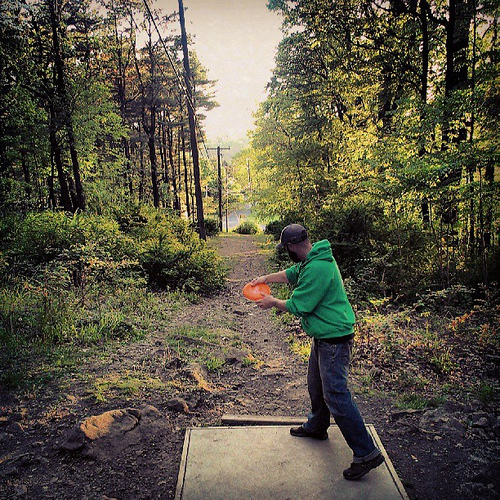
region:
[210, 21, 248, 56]
this is the sky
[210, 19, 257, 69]
the sky is bright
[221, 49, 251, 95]
the sky has clouds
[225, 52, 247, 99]
the clouds are white in color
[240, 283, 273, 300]
this is a frisbee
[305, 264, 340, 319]
the hood is green in color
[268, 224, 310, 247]
this is a cap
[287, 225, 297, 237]
the cap is black in color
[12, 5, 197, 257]
these are some trees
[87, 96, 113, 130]
the leaves are green in color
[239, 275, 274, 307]
An orange colored freesbee.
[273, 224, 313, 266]
A man wearing a black cap.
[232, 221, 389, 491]
A man in a green jacket.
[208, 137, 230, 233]
A telephone communications pole.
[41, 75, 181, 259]
Green foiliage in the woods.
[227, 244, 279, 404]
A bare dirt road.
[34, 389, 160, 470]
Footprints in the side of the road.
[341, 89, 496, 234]
The sun shining through the trees.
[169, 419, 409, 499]
A wooden platform in the woods.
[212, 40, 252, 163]
A gray colored sky with no clouds.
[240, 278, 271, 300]
an orange colored Frisbee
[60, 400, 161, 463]
brown colored rocks on the ground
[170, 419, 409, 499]
a wooden platform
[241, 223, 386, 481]
a man wearing blue jeans and a cap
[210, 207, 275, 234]
a body of water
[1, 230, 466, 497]
a dirt path in the woods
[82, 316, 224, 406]
green grass growing on the dirt path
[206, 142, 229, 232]
a utility pole beside the dirt path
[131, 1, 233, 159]
utility lines overhead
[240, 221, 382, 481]
a man wearing a green shirt and holding a Frisbee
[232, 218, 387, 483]
man is throwing a frisbee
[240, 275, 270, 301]
the frisbee is orange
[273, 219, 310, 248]
man is wearing a hat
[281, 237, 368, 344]
man's hoodie is green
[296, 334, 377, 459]
man is wearing blue jeans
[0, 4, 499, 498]
man is standing in the woods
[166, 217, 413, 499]
man is standing on concrete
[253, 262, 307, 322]
man's sleeves are pulled back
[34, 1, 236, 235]
electricity poles on side of forest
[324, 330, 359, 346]
man's undershirt is black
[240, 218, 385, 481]
this is a person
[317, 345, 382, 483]
this is a person's leg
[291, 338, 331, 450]
this is a person's leg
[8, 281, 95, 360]
this is a green vegetation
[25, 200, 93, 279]
this is a green vegetation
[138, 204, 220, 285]
this is a green vegetation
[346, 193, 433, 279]
this is a green vegetation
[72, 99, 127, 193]
this is a green vegetation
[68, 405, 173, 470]
this is a rock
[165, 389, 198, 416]
this is a rock